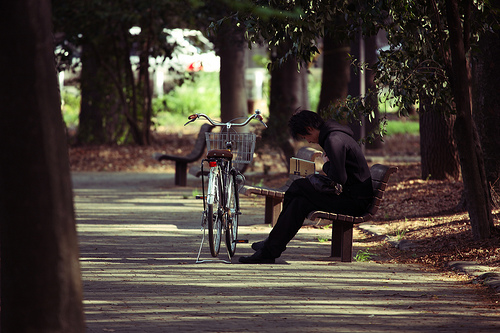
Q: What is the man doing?
A: Sitting.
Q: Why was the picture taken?
A: To show the man sitting.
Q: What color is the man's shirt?
A: Black.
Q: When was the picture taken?
A: In the daytime.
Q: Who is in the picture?
A: A man.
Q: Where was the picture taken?
A: In a park.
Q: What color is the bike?
A: Black and silver.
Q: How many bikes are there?
A: 1.